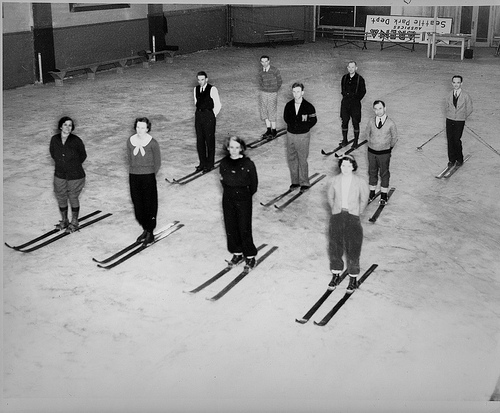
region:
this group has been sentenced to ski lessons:
[16, 45, 491, 332]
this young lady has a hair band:
[331, 150, 361, 179]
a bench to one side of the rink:
[30, 38, 183, 88]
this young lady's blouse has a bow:
[122, 113, 166, 180]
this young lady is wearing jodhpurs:
[44, 112, 89, 242]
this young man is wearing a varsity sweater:
[278, 80, 318, 191]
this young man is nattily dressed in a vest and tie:
[186, 70, 221, 174]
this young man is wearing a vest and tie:
[359, 97, 404, 207]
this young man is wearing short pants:
[251, 50, 284, 140]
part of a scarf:
[130, 142, 160, 158]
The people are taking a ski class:
[30, 33, 490, 368]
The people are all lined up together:
[18, 40, 478, 400]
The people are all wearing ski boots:
[25, 28, 497, 385]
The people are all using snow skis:
[35, 30, 446, 363]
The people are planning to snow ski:
[21, 45, 483, 372]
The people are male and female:
[30, 36, 487, 382]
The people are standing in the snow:
[45, 27, 485, 407]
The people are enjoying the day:
[30, 27, 469, 370]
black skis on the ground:
[295, 295, 347, 333]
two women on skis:
[184, 135, 412, 323]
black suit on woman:
[212, 151, 263, 252]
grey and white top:
[121, 121, 168, 181]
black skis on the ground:
[5, 206, 100, 271]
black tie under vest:
[365, 115, 395, 160]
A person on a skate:
[81, 90, 178, 243]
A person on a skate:
[368, 98, 398, 203]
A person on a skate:
[181, 52, 222, 172]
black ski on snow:
[314, 259, 378, 328]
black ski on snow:
[294, 265, 349, 324]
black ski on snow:
[206, 246, 280, 301]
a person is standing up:
[45, 102, 85, 231]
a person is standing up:
[127, 113, 164, 243]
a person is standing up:
[217, 137, 262, 268]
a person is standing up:
[327, 156, 362, 293]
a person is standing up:
[193, 70, 219, 175]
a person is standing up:
[278, 85, 317, 190]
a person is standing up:
[368, 97, 392, 207]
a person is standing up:
[447, 69, 470, 172]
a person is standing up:
[333, 56, 372, 148]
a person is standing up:
[246, 47, 286, 147]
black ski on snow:
[317, 263, 376, 328]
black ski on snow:
[292, 261, 345, 328]